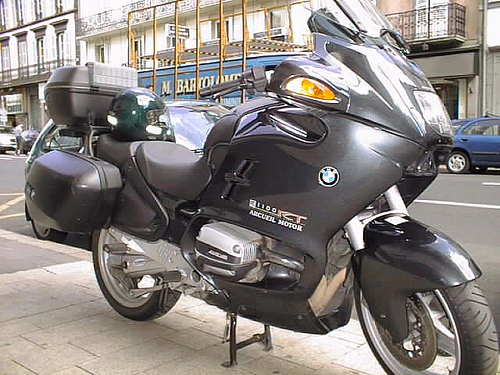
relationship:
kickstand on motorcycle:
[222, 310, 273, 369] [29, 0, 500, 374]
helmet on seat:
[107, 85, 178, 143] [99, 132, 212, 202]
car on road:
[439, 115, 499, 174] [0, 152, 500, 336]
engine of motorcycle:
[189, 221, 271, 286] [29, 0, 500, 374]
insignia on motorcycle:
[318, 166, 340, 188] [29, 0, 500, 374]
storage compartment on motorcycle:
[42, 60, 139, 131] [29, 0, 500, 374]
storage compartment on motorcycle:
[25, 150, 124, 234] [29, 0, 500, 374]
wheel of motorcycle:
[350, 267, 499, 375] [29, 0, 500, 374]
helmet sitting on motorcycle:
[107, 85, 178, 143] [29, 0, 500, 374]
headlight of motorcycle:
[413, 87, 454, 139] [29, 0, 500, 374]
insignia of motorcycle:
[318, 166, 340, 188] [29, 0, 500, 374]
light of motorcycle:
[282, 75, 339, 103] [29, 0, 500, 374]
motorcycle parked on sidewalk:
[29, 0, 500, 374] [0, 227, 458, 374]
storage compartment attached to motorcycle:
[42, 60, 139, 131] [29, 0, 500, 374]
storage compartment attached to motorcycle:
[25, 150, 124, 234] [29, 0, 500, 374]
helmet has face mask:
[107, 85, 178, 143] [148, 107, 177, 142]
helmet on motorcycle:
[107, 85, 178, 143] [29, 0, 500, 374]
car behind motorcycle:
[23, 98, 235, 246] [29, 0, 500, 374]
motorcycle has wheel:
[29, 0, 500, 374] [350, 267, 499, 375]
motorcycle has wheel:
[29, 0, 500, 374] [90, 229, 183, 323]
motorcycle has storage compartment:
[29, 0, 500, 374] [42, 60, 139, 131]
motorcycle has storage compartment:
[29, 0, 500, 374] [25, 150, 124, 234]